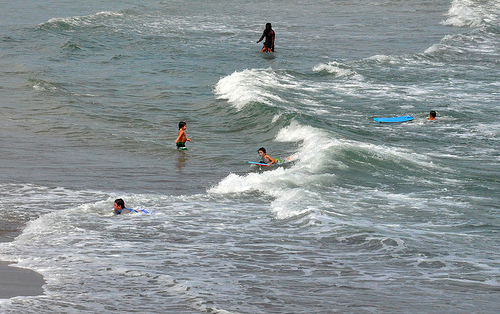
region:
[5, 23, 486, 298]
water with people in it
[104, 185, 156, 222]
person lying on board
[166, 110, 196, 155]
person standing in water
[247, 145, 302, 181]
person on board in water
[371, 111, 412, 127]
board in the water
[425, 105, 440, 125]
person in the water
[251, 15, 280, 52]
person standing in water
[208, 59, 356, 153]
ripple of the water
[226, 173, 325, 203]
white wave of water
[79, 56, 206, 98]
blue wave of water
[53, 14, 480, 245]
photograph taken at the beach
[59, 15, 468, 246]
people enjoying the ocean water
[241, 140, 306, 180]
person on a blue body board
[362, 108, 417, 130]
blue body board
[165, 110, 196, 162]
person walking in ocean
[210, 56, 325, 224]
ocean waves with white caps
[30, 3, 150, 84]
small waves in ocean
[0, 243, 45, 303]
wet sand of beach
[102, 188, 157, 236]
person laying on sand in ocean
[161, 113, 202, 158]
person wearing swim trunks and no shirt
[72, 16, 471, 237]
people surfing in the ocean waves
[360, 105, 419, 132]
bright blue surfboard floating in the water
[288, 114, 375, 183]
foam on the ocean water waves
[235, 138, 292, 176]
young boy floating on a surfboard on the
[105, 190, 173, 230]
boy swimming in the ocean in blue wetsuit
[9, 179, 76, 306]
shallow waves washing up on the sand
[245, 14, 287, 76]
tall man standing in the ocean water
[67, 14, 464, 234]
five people in the water at the ocean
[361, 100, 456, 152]
person next to surfboard in ocean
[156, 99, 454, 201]
boys with surfboards in the ocean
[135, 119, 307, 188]
this is a group of people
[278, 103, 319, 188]
the waves are white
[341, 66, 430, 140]
this is a surfboard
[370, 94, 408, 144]
the board is blue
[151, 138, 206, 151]
this is a bathing suit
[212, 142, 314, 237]
the sun is shining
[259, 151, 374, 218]
these are beach waves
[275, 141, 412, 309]
this is salt water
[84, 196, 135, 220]
the hair is short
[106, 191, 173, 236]
the hair is brown